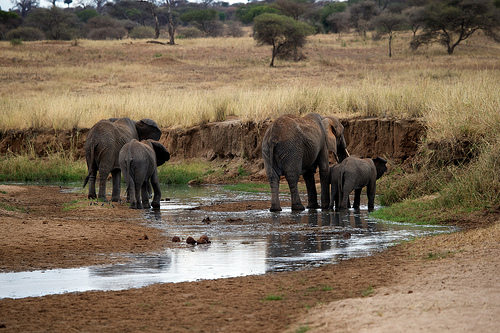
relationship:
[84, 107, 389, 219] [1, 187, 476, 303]
elephants near water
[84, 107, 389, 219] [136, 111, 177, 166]
elephants have large ears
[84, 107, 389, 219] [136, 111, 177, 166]
elephants with large ears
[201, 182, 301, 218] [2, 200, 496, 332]
island of dirt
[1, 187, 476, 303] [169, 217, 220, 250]
water has rocks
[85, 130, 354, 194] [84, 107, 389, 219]
rears of elephants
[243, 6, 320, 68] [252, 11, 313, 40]
bushes has green leaves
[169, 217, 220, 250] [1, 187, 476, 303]
rocks in water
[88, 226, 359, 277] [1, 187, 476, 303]
reflection of water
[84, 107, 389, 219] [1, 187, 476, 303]
elephants in water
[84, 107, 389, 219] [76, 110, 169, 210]
elephants stand in pairs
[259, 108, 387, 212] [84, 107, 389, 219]
pair of elephants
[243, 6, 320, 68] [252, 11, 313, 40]
bushes with green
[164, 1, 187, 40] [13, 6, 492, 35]
tree in bushes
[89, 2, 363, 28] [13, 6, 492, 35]
trees in background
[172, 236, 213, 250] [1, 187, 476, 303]
feces in water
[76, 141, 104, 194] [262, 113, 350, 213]
tail of elephant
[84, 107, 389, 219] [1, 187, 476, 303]
elephants drink water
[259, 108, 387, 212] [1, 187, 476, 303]
pair in water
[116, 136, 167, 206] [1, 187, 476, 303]
small elephant in water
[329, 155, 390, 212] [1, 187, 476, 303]
small elephant in water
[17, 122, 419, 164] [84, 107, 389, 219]
ledge in front of elephants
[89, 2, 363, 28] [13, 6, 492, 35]
trees in bushes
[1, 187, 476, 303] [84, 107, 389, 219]
water for animals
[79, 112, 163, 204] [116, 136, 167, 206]
elephants walking with baby elephant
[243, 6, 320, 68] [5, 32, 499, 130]
bushes in savannah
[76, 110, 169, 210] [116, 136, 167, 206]
elephant with older baby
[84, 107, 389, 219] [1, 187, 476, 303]
elephants at water hole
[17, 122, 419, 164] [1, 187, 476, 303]
eroding soil near water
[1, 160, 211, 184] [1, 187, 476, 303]
green grass near water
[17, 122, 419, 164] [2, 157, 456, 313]
ledge overlooking water